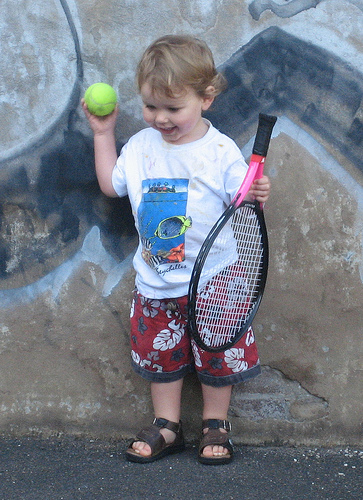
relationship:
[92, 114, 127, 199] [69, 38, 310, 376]
arm of person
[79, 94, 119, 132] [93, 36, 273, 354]
hand of person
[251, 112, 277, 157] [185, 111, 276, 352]
handle on racket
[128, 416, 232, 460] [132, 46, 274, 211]
feet of person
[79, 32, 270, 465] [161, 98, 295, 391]
boy holding racket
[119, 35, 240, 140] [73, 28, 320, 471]
head of a person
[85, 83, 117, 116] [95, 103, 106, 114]
ball with stain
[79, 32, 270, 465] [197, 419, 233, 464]
boy with sandal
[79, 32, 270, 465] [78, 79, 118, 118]
boy holding tennis ball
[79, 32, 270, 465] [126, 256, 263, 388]
boy with shorts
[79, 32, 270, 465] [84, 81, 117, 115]
boy with ball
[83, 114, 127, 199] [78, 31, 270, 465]
arm belonging to person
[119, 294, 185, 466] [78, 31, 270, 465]
leg belonging to person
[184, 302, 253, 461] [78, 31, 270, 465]
leg belonging to person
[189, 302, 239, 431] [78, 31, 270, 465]
leg belonging to person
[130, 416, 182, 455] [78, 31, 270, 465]
feet belonging to person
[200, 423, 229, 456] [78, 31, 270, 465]
foot belonging to person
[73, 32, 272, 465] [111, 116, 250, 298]
boy wearing shirt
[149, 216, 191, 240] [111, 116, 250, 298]
fish adorning shirt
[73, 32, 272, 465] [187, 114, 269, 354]
boy holding racket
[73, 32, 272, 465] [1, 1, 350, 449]
boy standing next to wall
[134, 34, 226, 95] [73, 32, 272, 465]
blonde hair belonging to boy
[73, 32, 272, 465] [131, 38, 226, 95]
boy has blonde hair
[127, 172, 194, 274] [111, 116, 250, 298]
picture on shirt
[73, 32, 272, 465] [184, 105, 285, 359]
boy holding racket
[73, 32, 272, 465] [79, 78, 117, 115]
boy holding ball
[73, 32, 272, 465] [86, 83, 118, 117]
boy holding ball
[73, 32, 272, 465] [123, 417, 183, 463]
boy wearing sandal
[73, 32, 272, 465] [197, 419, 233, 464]
boy wearing sandal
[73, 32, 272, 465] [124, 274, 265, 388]
boy wearing shorts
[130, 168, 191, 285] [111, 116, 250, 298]
print on shirt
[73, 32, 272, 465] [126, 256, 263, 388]
boy wearing shorts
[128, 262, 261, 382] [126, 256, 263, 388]
print on shorts